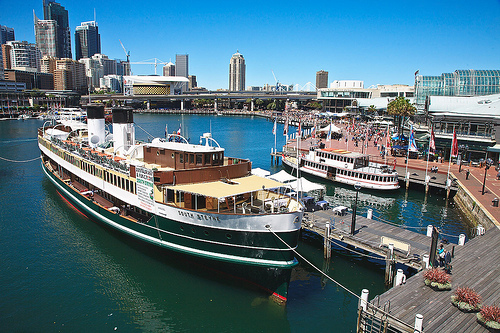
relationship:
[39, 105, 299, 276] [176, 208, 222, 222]
boat has name